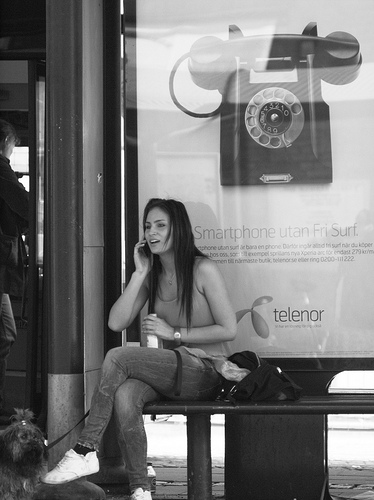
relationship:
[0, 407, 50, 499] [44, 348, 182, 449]
dog on a leash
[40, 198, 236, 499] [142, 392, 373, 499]
woman sitting on bench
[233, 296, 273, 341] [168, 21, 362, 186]
logo under telephone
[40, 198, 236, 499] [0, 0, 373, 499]
woman sitting in a bus stop shelter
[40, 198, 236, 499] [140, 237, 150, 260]
woman using a cell phone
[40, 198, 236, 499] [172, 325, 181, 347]
woman wearing a wristwatch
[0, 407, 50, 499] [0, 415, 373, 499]
dog on ground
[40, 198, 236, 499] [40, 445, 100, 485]
woman wearing a sneaker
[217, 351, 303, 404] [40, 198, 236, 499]
purse next to woman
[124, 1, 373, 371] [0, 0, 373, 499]
advertisement at bus stop shelter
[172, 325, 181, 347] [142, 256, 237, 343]
wristwatch on left arm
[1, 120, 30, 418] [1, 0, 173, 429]
passenger boarding bus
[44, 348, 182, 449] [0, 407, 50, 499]
leash attached to dog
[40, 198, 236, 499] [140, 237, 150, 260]
woman holding cell phone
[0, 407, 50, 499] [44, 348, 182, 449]
dog attached to a leash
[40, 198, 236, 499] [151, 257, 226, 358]
woman wearing a tanktop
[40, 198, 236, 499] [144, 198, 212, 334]
woman has hair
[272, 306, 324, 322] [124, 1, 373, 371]
telenor on advertisement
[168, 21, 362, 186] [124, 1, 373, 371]
telephone on advertisement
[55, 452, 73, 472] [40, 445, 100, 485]
lace on sneaker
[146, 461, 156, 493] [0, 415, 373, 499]
bottle on ground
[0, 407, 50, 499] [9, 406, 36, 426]
dog has a ponytail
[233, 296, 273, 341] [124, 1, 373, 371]
logo on advertisement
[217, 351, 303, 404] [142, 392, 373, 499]
purse on bench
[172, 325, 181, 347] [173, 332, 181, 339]
wristwatch has a white face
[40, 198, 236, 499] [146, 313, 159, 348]
woman holding object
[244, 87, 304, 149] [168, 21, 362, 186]
dial on telephone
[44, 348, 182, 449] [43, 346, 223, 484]
leash on woman's leg